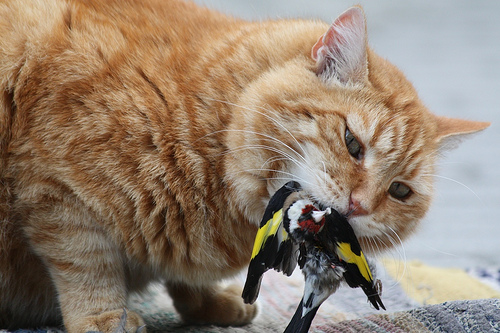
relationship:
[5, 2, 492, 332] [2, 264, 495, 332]
cat standing on bench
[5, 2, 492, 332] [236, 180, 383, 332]
cat holding bird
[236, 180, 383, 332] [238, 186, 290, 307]
bird has wing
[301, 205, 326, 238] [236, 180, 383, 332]
blood on head of bird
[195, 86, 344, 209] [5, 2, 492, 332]
whiskers are on face of cat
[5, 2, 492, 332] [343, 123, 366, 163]
cat has eye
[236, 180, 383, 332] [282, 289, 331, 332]
bird has tail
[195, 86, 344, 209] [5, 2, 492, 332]
whiskers are attached to cat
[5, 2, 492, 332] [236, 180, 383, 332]
cat eating bird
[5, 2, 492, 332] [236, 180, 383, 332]
cat looking at bird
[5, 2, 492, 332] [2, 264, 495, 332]
cat standing on rug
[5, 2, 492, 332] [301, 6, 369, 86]
cat has ear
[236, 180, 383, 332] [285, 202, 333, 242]
bird has head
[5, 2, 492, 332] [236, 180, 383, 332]
cat carrying bird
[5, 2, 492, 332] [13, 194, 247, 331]
cat has legs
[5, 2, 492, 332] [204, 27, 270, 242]
cat has neck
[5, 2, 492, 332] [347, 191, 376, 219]
cat has nose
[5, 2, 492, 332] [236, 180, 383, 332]
cat chewing on bird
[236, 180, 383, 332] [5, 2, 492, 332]
bird being eaten by cat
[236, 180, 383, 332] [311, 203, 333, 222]
bird has beak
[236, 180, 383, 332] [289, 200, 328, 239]
bird has face